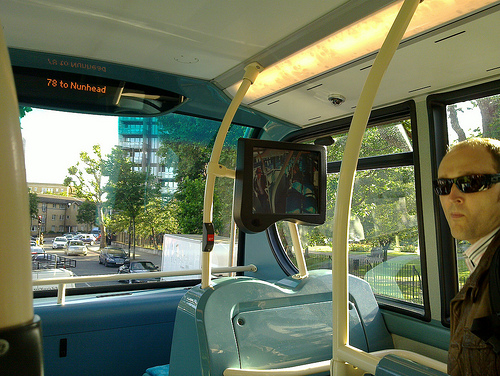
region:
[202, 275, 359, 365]
reflection on the bus seat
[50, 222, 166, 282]
cars are parked on the street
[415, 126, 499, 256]
man is wearing sunglasses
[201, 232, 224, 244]
a red call button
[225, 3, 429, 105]
light over head on the bus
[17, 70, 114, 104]
where the bus is going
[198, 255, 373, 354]
the bus seat is aqua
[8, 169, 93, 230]
a short yellowish building in the background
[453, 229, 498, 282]
the shirt is striped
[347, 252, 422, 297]
the fence is black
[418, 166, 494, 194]
SUNGLASSES ON MAN ON BUS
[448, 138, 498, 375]
BALD MAN RIDING CITY BUS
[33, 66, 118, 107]
DIGITAL STREET READ OUT ON BUS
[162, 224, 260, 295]
WHITE BOX TRUCK ON STREET AHEAD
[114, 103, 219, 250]
TALL BUILDING WITH GLASS WINDOWS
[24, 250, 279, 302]
WHITE SAFETY RAIL IN BUS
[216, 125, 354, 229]
BLACK TELIVISION IN CITY BUS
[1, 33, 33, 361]
DRIVER'S SEAT OF CITY BUS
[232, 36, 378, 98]
ILLUMINATED OVERHEAD LIGHT IN BUS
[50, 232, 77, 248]
SMALL WHITE CAR ON STREET AHEAD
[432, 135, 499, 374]
A man wearing sunglasses with very little hair.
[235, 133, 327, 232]
A black video monitor.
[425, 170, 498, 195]
Black sunglasses on a man's face.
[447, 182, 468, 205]
Nose on a man's face.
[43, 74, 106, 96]
78 to Nunhead in orange color at the front of the bus.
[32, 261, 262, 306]
White rail at the bottom of the front window.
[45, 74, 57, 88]
Orange number 78 above the windshield.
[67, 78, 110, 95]
Nunhead in orange letters.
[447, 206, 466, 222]
Lips on the face of a man wearing black glasses.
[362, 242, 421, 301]
A sidewalk curved to the right out a side window.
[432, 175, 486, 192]
sun glasses on man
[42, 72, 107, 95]
neon sign on bus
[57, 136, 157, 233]
front window on bus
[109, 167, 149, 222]
leaves on tree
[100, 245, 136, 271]
cars in the traffic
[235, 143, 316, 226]
mirror on the bus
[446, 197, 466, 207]
nose on the man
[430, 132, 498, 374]
passenger on the bus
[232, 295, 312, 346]
part of bus seat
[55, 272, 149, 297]
rail on the bus in front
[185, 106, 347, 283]
a tv on a bus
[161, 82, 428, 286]
a tv inside a bus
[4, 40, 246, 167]
a mirror on the bus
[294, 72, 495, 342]
a man on a bus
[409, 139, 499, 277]
a man wearing glasses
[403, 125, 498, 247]
a man wearing sun glasses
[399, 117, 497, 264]
a man with short hair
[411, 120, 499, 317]
a man wearing a shirt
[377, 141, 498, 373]
a man wearing a jacket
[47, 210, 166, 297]
vehicles on the road